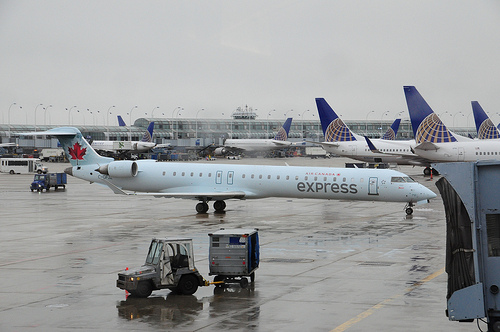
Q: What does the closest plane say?
A: Express.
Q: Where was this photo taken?
A: An airport.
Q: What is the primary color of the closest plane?
A: White.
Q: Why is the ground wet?
A: Rain.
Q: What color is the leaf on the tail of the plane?
A: Red.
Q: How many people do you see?
A: Zero.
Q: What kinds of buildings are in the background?
A: Terminals.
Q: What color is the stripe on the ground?
A: Yellow.